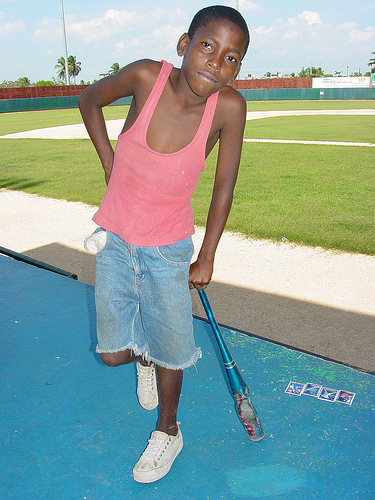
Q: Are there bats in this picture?
A: Yes, there is a bat.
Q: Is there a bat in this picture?
A: Yes, there is a bat.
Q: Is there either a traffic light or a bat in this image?
A: Yes, there is a bat.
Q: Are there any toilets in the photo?
A: No, there are no toilets.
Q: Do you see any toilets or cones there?
A: No, there are no toilets or cones.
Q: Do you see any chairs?
A: No, there are no chairs.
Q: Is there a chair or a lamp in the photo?
A: No, there are no chairs or lamps.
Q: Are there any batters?
A: No, there are no batters.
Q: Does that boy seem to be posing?
A: Yes, the boy is posing.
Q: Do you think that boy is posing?
A: Yes, the boy is posing.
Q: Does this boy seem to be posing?
A: Yes, the boy is posing.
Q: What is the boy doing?
A: The boy is posing.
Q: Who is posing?
A: The boy is posing.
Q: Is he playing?
A: No, the boy is posing.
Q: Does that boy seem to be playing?
A: No, the boy is posing.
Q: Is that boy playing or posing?
A: The boy is posing.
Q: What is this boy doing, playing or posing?
A: The boy is posing.